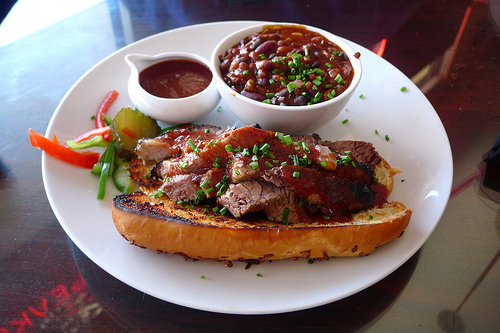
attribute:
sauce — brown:
[266, 151, 329, 200]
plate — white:
[49, 9, 448, 321]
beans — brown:
[238, 35, 301, 91]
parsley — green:
[229, 141, 284, 173]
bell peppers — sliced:
[48, 129, 119, 203]